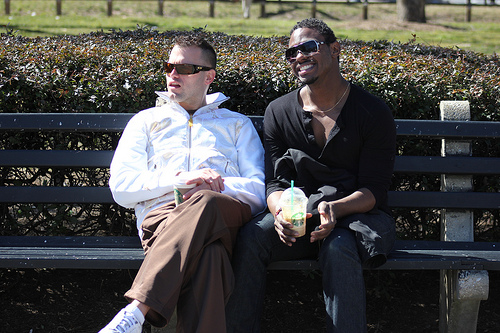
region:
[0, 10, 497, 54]
the path for people and animals to walk on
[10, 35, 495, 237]
the grassy area behind the bench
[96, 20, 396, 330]
the two people sitting on the bench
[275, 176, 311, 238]
the beverage container the person is holding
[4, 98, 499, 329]
the wooden bench the people are sitting on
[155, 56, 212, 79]
the sunglasses on the man's face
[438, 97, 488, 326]
the stone leg of the bench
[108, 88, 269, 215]
the jacket the man is wearing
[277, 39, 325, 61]
the sunglasses on the other man's face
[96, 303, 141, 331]
the shoe on the man's foot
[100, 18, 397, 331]
two men sitting on a bench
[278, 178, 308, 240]
man holding a plastic cup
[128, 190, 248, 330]
man crossing his legs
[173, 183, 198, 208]
man holding a green and white plastic cup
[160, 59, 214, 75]
man wearing black sunglasses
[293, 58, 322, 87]
man with a black goatee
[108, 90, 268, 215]
man wearing a white zipper jacket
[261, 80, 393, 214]
man wearing a black long sleeve shirt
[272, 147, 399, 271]
man holding a jacket on his lap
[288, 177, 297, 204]
a green straw on a plastic cup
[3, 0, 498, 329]
a scene at the park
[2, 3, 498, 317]
a scene outside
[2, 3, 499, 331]
an image during the day time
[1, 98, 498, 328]
a black park bench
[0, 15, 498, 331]
two people sitting on a bench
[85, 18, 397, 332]
two people looking at the same direction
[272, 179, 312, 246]
a plastic cup from Starbucks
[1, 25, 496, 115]
some hedges behind the bench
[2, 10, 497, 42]
a field in the distance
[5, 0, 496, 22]
a fence in the background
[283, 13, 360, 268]
this is a man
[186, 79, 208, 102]
the man is light skinned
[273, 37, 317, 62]
this is a spectacle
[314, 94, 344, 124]
this is a necklace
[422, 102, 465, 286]
this is a bench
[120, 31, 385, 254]
the men are two in number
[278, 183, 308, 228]
this is a container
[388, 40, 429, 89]
this is a tree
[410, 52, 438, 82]
the leaves are green in color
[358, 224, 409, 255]
this is a jacket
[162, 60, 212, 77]
the man is wearing sunglasses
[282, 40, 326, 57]
the man is wearing sunglasses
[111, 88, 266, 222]
the man is wearing a jacket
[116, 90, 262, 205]
the jacket is white in color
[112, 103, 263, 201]
the man has his arms crossed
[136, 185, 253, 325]
the man is wearing long pants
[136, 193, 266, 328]
the pants are brown in color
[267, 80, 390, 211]
the man is wearing a long sleeve shirt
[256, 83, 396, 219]
the shirt is black in color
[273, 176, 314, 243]
the man is holding a cup